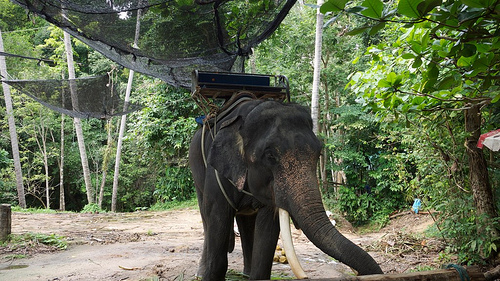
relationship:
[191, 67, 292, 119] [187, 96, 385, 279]
seat on elephant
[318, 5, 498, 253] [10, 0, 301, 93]
tree with net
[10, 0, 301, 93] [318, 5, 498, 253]
net on tree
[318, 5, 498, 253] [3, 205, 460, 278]
tree by ground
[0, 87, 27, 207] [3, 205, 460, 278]
stump on ground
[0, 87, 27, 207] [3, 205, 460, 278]
stump in ground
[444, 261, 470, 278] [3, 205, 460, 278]
plastic on ground